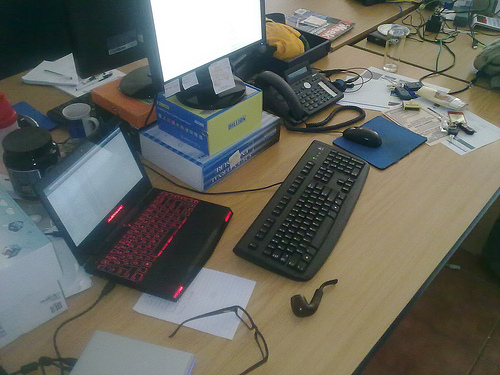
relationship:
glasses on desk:
[171, 305, 285, 370] [102, 99, 489, 279]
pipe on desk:
[279, 276, 344, 311] [102, 99, 489, 279]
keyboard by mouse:
[230, 139, 369, 282] [341, 124, 381, 147]